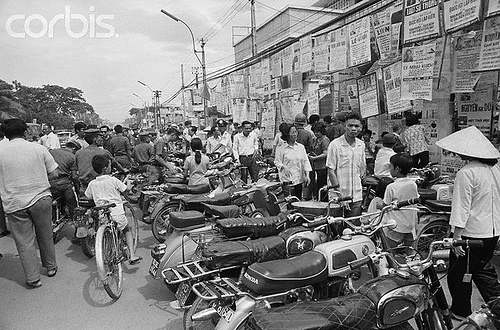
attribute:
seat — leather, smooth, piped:
[244, 290, 376, 328]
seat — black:
[203, 227, 320, 269]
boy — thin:
[281, 126, 396, 198]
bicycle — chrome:
[80, 187, 141, 300]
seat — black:
[200, 234, 288, 267]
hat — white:
[436, 119, 493, 171]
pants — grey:
[0, 193, 58, 284]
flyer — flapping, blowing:
[399, 43, 436, 101]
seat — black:
[236, 244, 332, 296]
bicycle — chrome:
[68, 192, 145, 300]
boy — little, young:
[84, 154, 144, 263]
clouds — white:
[91, 55, 156, 67]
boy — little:
[83, 151, 147, 273]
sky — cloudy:
[2, 1, 176, 88]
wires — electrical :
[154, 0, 259, 97]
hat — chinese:
[431, 127, 497, 160]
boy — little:
[80, 148, 144, 265]